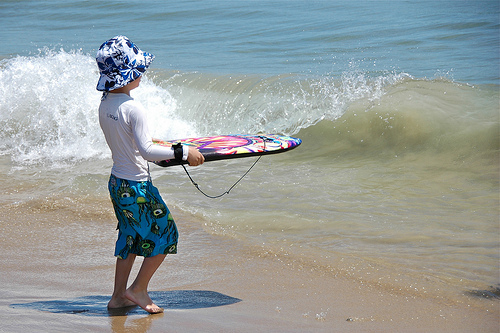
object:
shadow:
[10, 288, 240, 317]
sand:
[0, 201, 497, 331]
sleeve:
[127, 107, 190, 162]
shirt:
[98, 91, 190, 183]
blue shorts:
[107, 179, 178, 260]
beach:
[1, 190, 499, 330]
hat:
[95, 33, 156, 92]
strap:
[172, 144, 183, 165]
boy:
[95, 36, 206, 315]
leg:
[132, 207, 179, 286]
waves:
[1, 45, 499, 210]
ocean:
[2, 0, 498, 226]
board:
[152, 133, 302, 167]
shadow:
[459, 288, 499, 302]